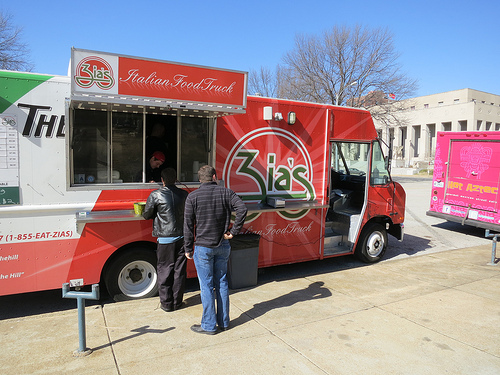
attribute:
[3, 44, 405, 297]
truck — red, parked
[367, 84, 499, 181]
building — far, brown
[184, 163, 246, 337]
person — standing, waiting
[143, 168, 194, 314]
person — standing, ordering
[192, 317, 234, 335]
shoes — black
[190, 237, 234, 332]
pants — blue, jean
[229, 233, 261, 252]
bag — black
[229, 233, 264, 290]
trashcan — gray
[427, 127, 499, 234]
truck — pink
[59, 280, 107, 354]
pole — blue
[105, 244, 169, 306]
tire — black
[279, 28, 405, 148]
tree — large, bare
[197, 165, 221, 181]
hair — short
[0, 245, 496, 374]
sidewalk — here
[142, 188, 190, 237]
jack — black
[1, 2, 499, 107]
sky — clear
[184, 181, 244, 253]
shirt — striped